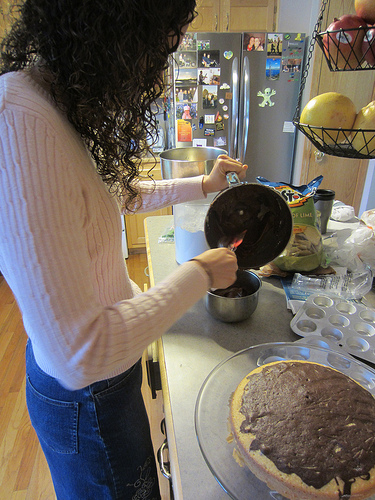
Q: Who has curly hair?
A: The woman.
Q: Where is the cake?
A: On a clear glass plate.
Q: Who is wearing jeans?
A: The woman.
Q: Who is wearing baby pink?
A: The woman.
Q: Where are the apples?
A: In a hanging basket.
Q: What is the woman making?
A: Frosting.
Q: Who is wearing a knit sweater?
A: The woman.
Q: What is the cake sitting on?
A: A glass plate.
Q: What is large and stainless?
A: The fridge.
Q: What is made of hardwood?
A: The floor.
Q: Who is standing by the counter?
A: A woman.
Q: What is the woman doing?
A: Frosting a cake.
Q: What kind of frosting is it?
A: Chocolate.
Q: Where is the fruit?
A: In hanging baskets.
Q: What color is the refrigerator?
A: Silver.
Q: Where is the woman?
A: In the kitchen.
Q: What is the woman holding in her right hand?
A: A spatula.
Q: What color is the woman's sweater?
A: White.